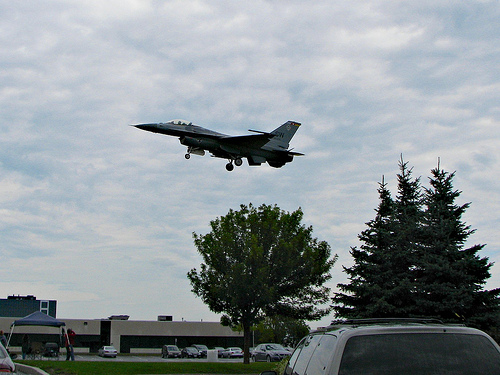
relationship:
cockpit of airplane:
[174, 118, 192, 135] [135, 104, 328, 167]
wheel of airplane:
[178, 146, 244, 174] [135, 104, 328, 167]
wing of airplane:
[226, 129, 286, 160] [135, 104, 328, 167]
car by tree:
[93, 346, 126, 370] [182, 188, 317, 352]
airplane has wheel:
[130, 119, 308, 173] [178, 146, 244, 174]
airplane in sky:
[130, 119, 308, 173] [123, 32, 247, 80]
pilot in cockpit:
[170, 116, 206, 149] [174, 118, 192, 135]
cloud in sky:
[211, 15, 312, 80] [123, 32, 247, 80]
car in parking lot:
[93, 346, 126, 370] [20, 334, 314, 366]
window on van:
[333, 301, 497, 374] [279, 317, 499, 375]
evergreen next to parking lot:
[411, 153, 500, 323] [24, 330, 292, 361]